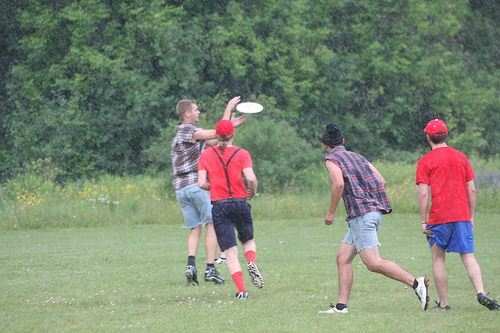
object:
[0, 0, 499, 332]
field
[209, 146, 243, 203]
suspenders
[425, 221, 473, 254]
shorts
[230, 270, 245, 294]
sock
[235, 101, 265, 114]
firsbee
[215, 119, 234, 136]
cap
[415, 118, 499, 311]
men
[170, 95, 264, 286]
man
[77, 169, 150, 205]
wildflower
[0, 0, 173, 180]
tree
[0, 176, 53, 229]
flowers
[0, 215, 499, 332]
grass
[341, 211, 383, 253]
jeans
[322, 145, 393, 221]
shirt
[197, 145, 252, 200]
shirt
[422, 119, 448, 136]
hat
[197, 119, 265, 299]
player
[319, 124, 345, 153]
head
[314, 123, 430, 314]
boy